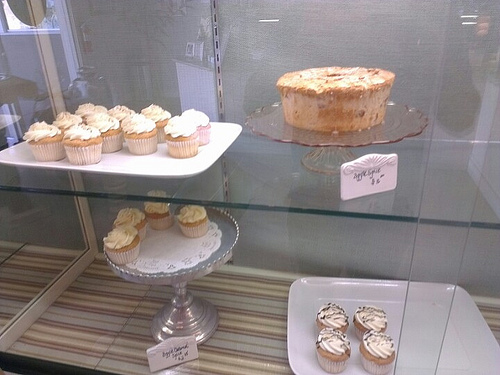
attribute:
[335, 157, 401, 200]
sign — white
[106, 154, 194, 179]
plate — white, large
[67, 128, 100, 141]
frosting — yellow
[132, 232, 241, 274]
platter — silver, metal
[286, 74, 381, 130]
cake — delicious, brown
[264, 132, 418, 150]
platter — glass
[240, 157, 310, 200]
shelf — clear, glass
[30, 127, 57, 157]
cupcake — delicious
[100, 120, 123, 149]
cupcake — delicious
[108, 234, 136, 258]
cupcake — delicious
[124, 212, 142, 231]
cupcake — delicious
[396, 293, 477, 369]
tray — glass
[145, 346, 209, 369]
sign — white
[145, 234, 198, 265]
doliy — white